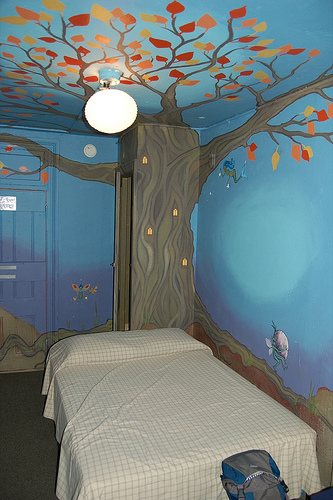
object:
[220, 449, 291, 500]
backpack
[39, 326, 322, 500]
bed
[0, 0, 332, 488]
painted mural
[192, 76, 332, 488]
wall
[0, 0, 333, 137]
ceiling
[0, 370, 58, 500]
floor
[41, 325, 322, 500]
bedspread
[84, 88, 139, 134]
light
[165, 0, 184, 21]
leaves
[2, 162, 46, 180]
branches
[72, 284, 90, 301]
butterfly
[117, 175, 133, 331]
closet door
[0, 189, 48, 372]
room door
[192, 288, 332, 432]
roots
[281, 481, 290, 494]
left snap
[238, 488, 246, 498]
right snap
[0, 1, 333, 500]
room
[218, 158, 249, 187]
mermaid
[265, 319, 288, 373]
alien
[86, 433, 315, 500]
edge